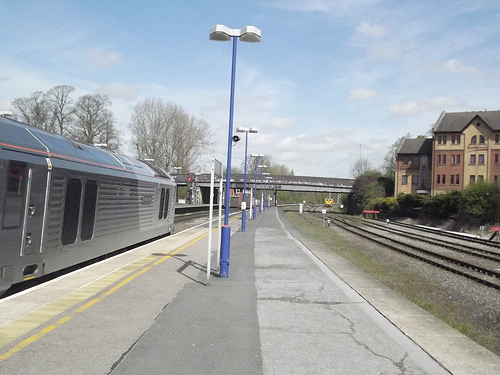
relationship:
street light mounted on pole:
[209, 24, 263, 44] [218, 37, 238, 277]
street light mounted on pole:
[235, 126, 259, 135] [242, 133, 252, 231]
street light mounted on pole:
[249, 152, 266, 160] [251, 159, 259, 219]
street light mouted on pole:
[258, 164, 269, 169] [251, 159, 259, 219]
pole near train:
[218, 37, 238, 277] [1, 115, 179, 297]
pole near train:
[242, 133, 252, 231] [1, 115, 179, 297]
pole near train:
[251, 159, 259, 219] [1, 115, 179, 297]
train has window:
[1, 115, 179, 297] [58, 180, 81, 245]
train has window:
[1, 115, 179, 297] [80, 180, 96, 240]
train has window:
[1, 115, 179, 297] [158, 186, 166, 221]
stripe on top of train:
[0, 142, 155, 176] [1, 115, 179, 297]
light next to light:
[210, 32, 230, 41] [238, 34, 261, 44]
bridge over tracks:
[173, 174, 357, 209] [306, 205, 499, 291]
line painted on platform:
[0, 217, 217, 367] [1, 204, 454, 374]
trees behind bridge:
[225, 156, 295, 175] [173, 174, 357, 209]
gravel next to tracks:
[334, 225, 499, 311] [306, 205, 499, 291]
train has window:
[1, 115, 179, 297] [163, 187, 171, 218]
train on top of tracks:
[1, 115, 179, 297] [174, 199, 242, 231]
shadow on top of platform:
[152, 251, 221, 287] [1, 204, 454, 374]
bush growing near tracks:
[457, 183, 499, 225] [306, 205, 499, 291]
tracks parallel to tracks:
[306, 205, 499, 291] [174, 199, 242, 231]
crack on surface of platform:
[318, 304, 411, 373] [1, 204, 454, 374]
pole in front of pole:
[218, 37, 238, 277] [242, 133, 252, 231]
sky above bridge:
[0, 2, 500, 178] [173, 174, 357, 209]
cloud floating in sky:
[380, 95, 462, 117] [0, 2, 500, 178]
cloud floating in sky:
[68, 44, 120, 67] [0, 2, 500, 178]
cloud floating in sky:
[354, 21, 392, 41] [0, 2, 500, 178]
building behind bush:
[431, 111, 500, 196] [419, 190, 461, 219]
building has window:
[431, 111, 500, 196] [479, 153, 486, 165]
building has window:
[431, 111, 500, 196] [470, 153, 477, 166]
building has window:
[431, 111, 500, 196] [456, 174, 461, 185]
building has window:
[431, 111, 500, 196] [480, 134, 486, 145]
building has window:
[431, 111, 500, 196] [435, 153, 440, 165]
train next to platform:
[1, 115, 179, 297] [1, 204, 454, 374]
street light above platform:
[209, 24, 263, 44] [1, 204, 454, 374]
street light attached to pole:
[209, 24, 263, 44] [218, 37, 238, 277]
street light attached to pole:
[235, 126, 259, 135] [242, 133, 252, 231]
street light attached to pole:
[249, 152, 266, 160] [251, 159, 259, 219]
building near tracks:
[431, 111, 500, 196] [306, 205, 499, 291]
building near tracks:
[393, 137, 432, 195] [306, 205, 499, 291]